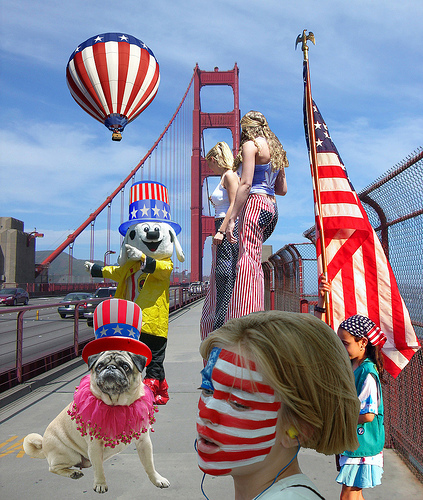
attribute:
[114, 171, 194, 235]
hat — american flag themed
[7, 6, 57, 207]
sky — blue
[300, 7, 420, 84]
clouds — white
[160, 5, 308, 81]
clouds — white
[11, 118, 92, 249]
clouds — white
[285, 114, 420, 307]
flag — american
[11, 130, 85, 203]
clouds — white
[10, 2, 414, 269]
sky — blue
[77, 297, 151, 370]
hat — american flag themed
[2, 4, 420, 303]
cloud — white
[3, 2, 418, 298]
sky — blue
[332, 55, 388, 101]
blue — sky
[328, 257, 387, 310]
flag — american flag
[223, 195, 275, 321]
pants — themed, american flag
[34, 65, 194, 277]
pole — red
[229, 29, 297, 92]
clouds — white